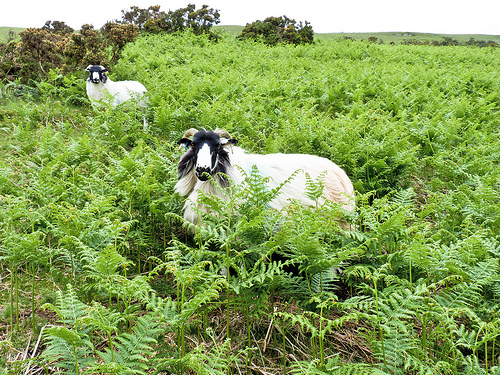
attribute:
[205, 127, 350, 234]
goat — black, white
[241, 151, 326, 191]
goat's fur — white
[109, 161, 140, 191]
fern — green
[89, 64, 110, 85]
face — sheep's, black, white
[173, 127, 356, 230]
fur — white, goat's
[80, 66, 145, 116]
goat — white, black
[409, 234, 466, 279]
fern — green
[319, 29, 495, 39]
hill — distant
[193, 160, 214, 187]
snout — goat's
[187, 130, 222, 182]
face — black, white, sheep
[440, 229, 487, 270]
fern — green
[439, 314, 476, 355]
fern — green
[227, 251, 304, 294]
fern — green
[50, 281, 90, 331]
fern — green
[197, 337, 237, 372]
fern — green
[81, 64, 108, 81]
face — black, white, sheep's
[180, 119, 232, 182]
face — white, black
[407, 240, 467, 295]
fern — green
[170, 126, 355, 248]
goat — closest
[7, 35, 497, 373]
fern — green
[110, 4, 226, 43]
tree — behind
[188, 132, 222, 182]
goat's face — white, black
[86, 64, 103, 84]
goat's face — white, black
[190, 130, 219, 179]
goat's face — black, white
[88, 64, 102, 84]
goat's face — black, white